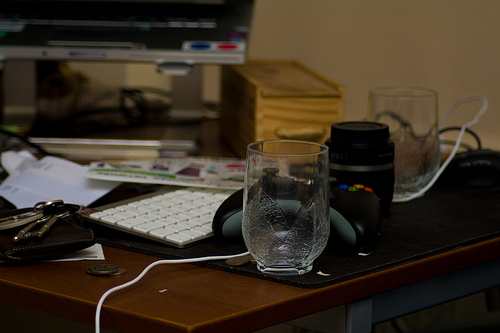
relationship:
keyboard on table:
[90, 195, 187, 255] [198, 274, 217, 299]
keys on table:
[0, 199, 79, 239] [195, 279, 217, 306]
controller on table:
[202, 170, 367, 273] [164, 283, 208, 317]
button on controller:
[326, 170, 365, 223] [212, 159, 369, 278]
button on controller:
[347, 177, 374, 205] [212, 159, 369, 278]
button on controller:
[336, 173, 365, 203] [221, 164, 378, 255]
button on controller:
[326, 167, 379, 208] [202, 170, 367, 273]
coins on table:
[89, 254, 143, 284] [148, 270, 239, 324]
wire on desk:
[92, 94, 491, 331] [1, 218, 494, 328]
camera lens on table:
[324, 112, 403, 192] [167, 281, 231, 310]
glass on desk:
[239, 137, 330, 277] [163, 276, 209, 317]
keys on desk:
[0, 199, 79, 239] [175, 284, 258, 321]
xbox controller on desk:
[209, 166, 387, 245] [1, 218, 494, 328]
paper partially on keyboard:
[88, 156, 253, 189] [74, 186, 238, 250]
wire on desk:
[92, 94, 491, 331] [5, 240, 498, 330]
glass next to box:
[367, 83, 442, 204] [213, 57, 347, 159]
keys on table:
[0, 199, 79, 239] [1, 233, 498, 332]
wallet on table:
[5, 209, 97, 262] [1, 233, 498, 332]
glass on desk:
[239, 137, 330, 277] [5, 240, 498, 330]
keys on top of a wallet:
[0, 199, 79, 239] [8, 212, 162, 275]